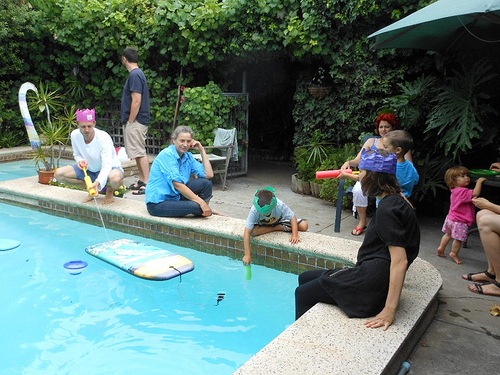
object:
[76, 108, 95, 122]
paper hat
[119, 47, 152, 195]
man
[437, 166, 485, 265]
toddler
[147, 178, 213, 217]
pants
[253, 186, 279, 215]
crown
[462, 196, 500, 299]
woman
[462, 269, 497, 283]
sandal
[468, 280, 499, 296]
sandal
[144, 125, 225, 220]
man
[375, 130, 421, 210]
boy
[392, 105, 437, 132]
ground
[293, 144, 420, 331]
woman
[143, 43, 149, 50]
foliage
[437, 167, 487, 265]
girl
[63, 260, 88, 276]
device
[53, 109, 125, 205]
man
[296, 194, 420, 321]
black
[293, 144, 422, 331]
man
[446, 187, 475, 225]
outfit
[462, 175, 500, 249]
table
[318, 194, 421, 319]
outfit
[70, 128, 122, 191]
outfit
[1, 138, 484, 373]
pool area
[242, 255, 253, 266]
hand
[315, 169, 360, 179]
object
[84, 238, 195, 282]
object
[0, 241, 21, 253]
object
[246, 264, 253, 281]
object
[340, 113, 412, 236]
person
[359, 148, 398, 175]
crown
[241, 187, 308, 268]
boy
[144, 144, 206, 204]
shirt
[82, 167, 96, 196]
gun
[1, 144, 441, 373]
pool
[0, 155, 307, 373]
water